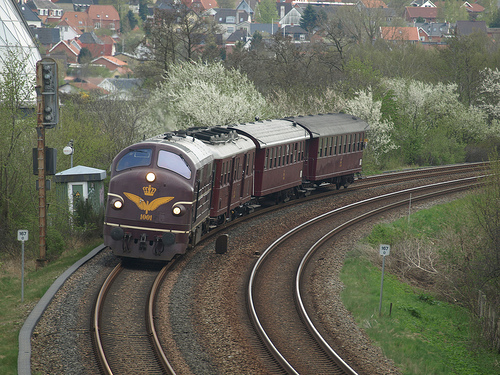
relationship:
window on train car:
[352, 137, 372, 156] [102, 109, 370, 262]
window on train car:
[356, 132, 364, 151] [102, 109, 370, 262]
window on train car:
[109, 145, 154, 172] [102, 109, 370, 262]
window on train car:
[160, 144, 188, 175] [102, 109, 370, 262]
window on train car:
[220, 163, 229, 187] [102, 109, 370, 262]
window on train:
[264, 143, 274, 173] [82, 74, 374, 311]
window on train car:
[272, 159, 278, 167] [102, 109, 370, 262]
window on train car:
[279, 157, 284, 165] [102, 109, 370, 262]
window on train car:
[296, 153, 300, 161] [102, 109, 370, 262]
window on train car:
[332, 146, 339, 157] [102, 109, 370, 262]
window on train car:
[357, 142, 363, 152] [102, 109, 370, 262]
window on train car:
[271, 145, 279, 168] [102, 109, 370, 262]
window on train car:
[283, 145, 293, 167] [102, 109, 370, 262]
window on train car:
[287, 140, 312, 172] [102, 109, 370, 262]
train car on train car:
[178, 126, 258, 219] [102, 109, 370, 262]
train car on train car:
[102, 109, 370, 262] [102, 109, 370, 262]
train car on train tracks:
[102, 109, 370, 262] [92, 158, 499, 373]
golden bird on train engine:
[120, 187, 177, 219] [111, 170, 190, 237]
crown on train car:
[140, 180, 157, 201] [102, 109, 370, 262]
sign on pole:
[18, 227, 29, 242] [18, 239, 27, 300]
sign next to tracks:
[18, 227, 29, 242] [88, 159, 495, 370]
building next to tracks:
[50, 163, 105, 235] [88, 159, 495, 370]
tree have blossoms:
[141, 53, 498, 178] [194, 82, 240, 120]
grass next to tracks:
[384, 224, 456, 354] [230, 228, 309, 335]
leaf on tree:
[445, 80, 459, 94] [378, 72, 487, 169]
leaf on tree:
[466, 103, 482, 115] [378, 72, 487, 169]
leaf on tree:
[413, 77, 427, 89] [378, 72, 487, 169]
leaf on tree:
[408, 92, 424, 106] [378, 72, 487, 169]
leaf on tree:
[435, 130, 448, 139] [378, 72, 487, 169]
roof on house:
[88, 54, 125, 64] [89, 55, 131, 77]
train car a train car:
[102, 109, 370, 262] [102, 109, 370, 262]